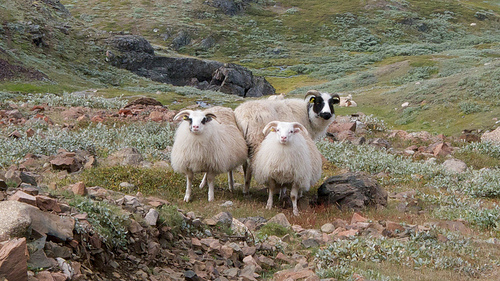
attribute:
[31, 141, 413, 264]
stones — brown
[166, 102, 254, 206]
goat — mountain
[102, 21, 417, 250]
sheep — fluffy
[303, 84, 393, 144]
face — black, white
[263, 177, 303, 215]
sheep legs — short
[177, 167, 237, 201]
sheep legs — short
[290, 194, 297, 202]
spot — Brown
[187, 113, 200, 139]
nose — pink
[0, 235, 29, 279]
rock — stuck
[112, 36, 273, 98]
rock — ON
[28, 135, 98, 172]
ground — rocky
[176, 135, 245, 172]
wool — white